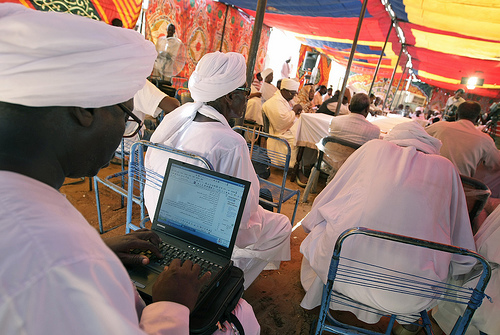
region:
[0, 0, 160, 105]
white turban on a head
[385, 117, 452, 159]
white turban on a head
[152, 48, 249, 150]
white turban on a head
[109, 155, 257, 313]
small black laptop computer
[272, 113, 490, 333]
person sitting in a chair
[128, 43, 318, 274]
person sitting in a chair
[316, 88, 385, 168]
person sitting in a chair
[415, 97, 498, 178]
person sitting in a chair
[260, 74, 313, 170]
person sitting in a chair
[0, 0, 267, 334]
person sitting in a chair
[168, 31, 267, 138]
white turban on head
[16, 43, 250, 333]
a man using a laptop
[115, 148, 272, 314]
an open small laptop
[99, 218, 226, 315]
fingers on the keyboard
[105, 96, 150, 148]
black framed glasses on face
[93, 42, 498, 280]
many people gathered in one room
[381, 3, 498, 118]
red and yellow cloth ceiling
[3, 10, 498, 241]
all men wearing white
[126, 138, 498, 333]
blue metal chairs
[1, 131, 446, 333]
a dirt floor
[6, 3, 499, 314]
men sitting in blue chairs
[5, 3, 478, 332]
group of men wearing white turbans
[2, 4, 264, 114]
mural painted on the wall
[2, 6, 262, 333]
man working a laptop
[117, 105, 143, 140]
black framed eye glasses of man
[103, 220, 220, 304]
man's hands on the keyboard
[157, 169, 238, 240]
screen of the laptop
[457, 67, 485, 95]
light at the front of the room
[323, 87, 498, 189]
two men wearing white shirts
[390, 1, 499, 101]
red and yellow stripes on the ceiling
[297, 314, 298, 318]
part of surface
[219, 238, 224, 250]
part of a laptop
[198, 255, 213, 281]
edge of a laptop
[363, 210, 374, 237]
part of a cloth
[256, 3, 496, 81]
colored fabric on ceiling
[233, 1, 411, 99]
poles holding up fabric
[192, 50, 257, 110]
white turban on head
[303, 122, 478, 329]
man in white slumped over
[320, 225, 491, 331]
back of metal chair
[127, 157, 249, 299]
inside of open laptop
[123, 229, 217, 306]
two hands on keyboard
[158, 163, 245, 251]
glowing screen on laptop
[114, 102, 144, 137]
glass on man's face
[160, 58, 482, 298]
people dressed in white